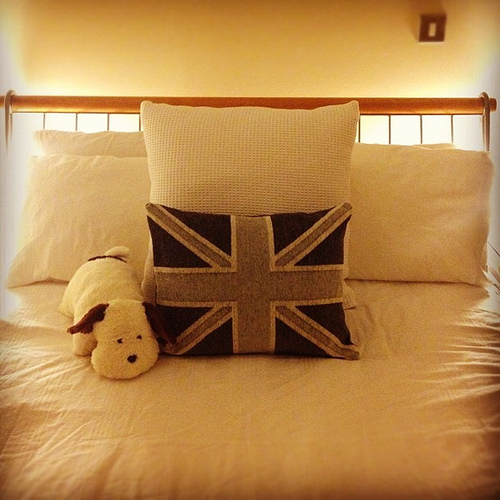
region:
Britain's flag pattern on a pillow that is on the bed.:
[142, 202, 360, 362]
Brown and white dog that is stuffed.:
[59, 243, 180, 380]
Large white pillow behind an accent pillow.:
[135, 95, 360, 315]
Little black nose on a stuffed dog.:
[122, 353, 141, 362]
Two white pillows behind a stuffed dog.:
[3, 128, 150, 290]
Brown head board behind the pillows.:
[2, 92, 499, 151]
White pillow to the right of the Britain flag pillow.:
[350, 145, 493, 286]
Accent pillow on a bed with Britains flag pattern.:
[140, 202, 363, 361]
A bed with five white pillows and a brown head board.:
[3, 92, 498, 496]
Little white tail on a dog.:
[102, 245, 132, 261]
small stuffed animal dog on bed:
[43, 232, 160, 389]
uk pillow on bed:
[139, 203, 354, 366]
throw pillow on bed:
[141, 101, 356, 206]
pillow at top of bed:
[346, 147, 481, 282]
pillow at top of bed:
[27, 142, 146, 271]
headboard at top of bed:
[3, 93, 478, 147]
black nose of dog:
[119, 354, 138, 366]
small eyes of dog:
[108, 333, 125, 350]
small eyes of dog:
[130, 330, 142, 345]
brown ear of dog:
[56, 301, 110, 333]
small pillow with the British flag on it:
[143, 200, 361, 360]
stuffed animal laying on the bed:
[54, 237, 168, 390]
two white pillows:
[15, 122, 156, 292]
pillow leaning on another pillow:
[14, 125, 151, 288]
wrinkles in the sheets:
[440, 299, 499, 399]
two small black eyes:
[107, 322, 150, 349]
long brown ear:
[58, 301, 113, 341]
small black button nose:
[122, 346, 142, 371]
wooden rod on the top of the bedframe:
[10, 86, 481, 121]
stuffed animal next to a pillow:
[54, 202, 385, 392]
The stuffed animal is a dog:
[36, 246, 176, 397]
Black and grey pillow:
[127, 191, 372, 359]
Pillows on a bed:
[8, 94, 495, 354]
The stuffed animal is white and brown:
[55, 258, 167, 387]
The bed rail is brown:
[0, 85, 494, 150]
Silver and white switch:
[408, 8, 461, 60]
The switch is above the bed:
[396, 3, 462, 60]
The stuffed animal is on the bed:
[56, 244, 195, 394]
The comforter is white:
[6, 217, 486, 495]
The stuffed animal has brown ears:
[69, 278, 181, 393]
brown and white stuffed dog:
[58, 249, 165, 380]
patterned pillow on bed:
[146, 201, 349, 356]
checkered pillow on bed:
[143, 103, 351, 209]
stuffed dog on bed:
[66, 247, 159, 379]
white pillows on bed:
[26, 128, 489, 288]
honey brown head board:
[1, 91, 497, 148]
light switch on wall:
[417, 12, 444, 42]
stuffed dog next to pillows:
[64, 248, 159, 380]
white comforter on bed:
[3, 284, 495, 499]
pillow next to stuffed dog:
[146, 200, 359, 357]